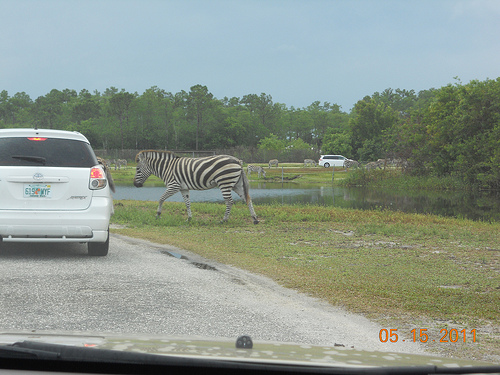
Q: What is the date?
A: 05/15/2011.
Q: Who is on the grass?
A: The zebra.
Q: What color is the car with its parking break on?
A: White.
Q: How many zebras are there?
A: 1.